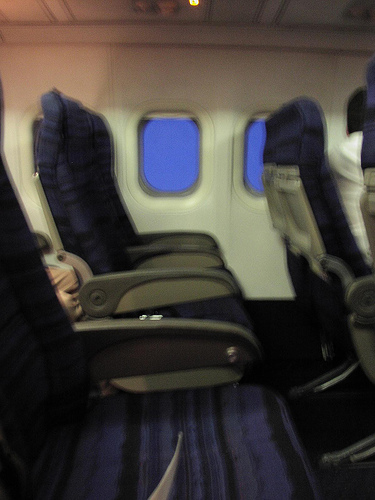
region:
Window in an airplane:
[135, 89, 219, 204]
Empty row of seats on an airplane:
[55, 95, 290, 344]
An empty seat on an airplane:
[4, 291, 272, 498]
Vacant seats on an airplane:
[7, 96, 305, 495]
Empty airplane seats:
[1, 78, 250, 492]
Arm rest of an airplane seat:
[61, 321, 255, 428]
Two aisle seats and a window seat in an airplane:
[10, 82, 291, 476]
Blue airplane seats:
[0, 111, 285, 496]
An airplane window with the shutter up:
[128, 91, 235, 207]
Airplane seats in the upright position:
[39, 83, 266, 311]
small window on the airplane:
[134, 103, 213, 196]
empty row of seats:
[27, 78, 264, 315]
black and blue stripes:
[68, 395, 298, 498]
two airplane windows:
[134, 101, 277, 208]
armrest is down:
[110, 238, 228, 268]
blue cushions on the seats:
[39, 86, 144, 259]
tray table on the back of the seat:
[271, 170, 331, 268]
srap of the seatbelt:
[129, 422, 208, 498]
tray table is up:
[274, 166, 335, 273]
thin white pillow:
[325, 132, 374, 264]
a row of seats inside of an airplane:
[9, 24, 289, 498]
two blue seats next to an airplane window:
[35, 80, 267, 316]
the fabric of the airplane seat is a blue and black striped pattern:
[87, 406, 300, 489]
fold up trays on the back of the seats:
[259, 159, 324, 269]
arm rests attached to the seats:
[140, 223, 239, 310]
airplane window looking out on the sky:
[129, 99, 209, 203]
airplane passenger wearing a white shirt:
[334, 87, 374, 242]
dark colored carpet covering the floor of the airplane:
[264, 322, 309, 386]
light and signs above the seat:
[125, 1, 212, 25]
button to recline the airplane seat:
[223, 346, 244, 365]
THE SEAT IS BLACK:
[0, 145, 330, 497]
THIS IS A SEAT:
[25, 89, 254, 346]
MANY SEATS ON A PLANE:
[1, 67, 370, 495]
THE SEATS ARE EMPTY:
[1, 68, 329, 499]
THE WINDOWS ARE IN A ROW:
[26, 101, 296, 210]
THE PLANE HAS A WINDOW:
[131, 101, 207, 210]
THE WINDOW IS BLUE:
[135, 96, 213, 205]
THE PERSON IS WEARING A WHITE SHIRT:
[327, 114, 372, 274]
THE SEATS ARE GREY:
[0, 89, 323, 498]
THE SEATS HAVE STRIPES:
[1, 81, 373, 499]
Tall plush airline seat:
[33, 89, 256, 337]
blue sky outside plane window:
[141, 111, 195, 195]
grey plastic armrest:
[84, 268, 233, 311]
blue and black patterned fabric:
[83, 397, 287, 499]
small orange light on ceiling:
[180, 0, 206, 9]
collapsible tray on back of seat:
[270, 170, 320, 263]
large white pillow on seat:
[326, 138, 370, 266]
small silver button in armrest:
[226, 347, 243, 367]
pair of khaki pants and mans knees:
[45, 255, 79, 321]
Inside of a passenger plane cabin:
[2, 8, 371, 480]